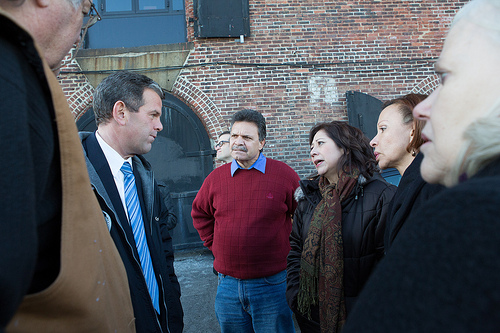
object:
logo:
[262, 192, 273, 200]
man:
[188, 107, 304, 331]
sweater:
[187, 160, 300, 278]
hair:
[91, 71, 166, 126]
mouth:
[310, 158, 325, 167]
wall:
[47, 0, 490, 240]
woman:
[283, 122, 397, 332]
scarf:
[295, 167, 366, 331]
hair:
[306, 120, 380, 182]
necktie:
[116, 161, 165, 315]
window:
[80, 11, 193, 48]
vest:
[1, 14, 138, 331]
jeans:
[213, 272, 298, 333]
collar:
[227, 153, 266, 178]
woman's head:
[304, 120, 369, 177]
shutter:
[194, 1, 251, 39]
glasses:
[79, 1, 103, 32]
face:
[46, 0, 94, 70]